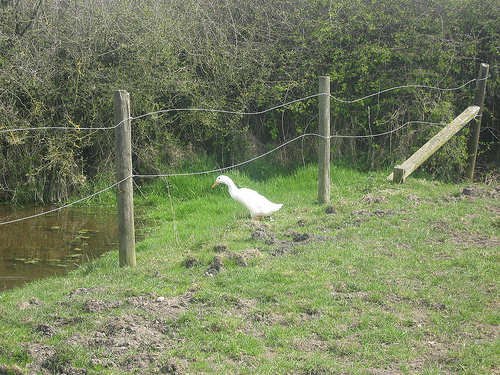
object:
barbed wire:
[0, 77, 491, 225]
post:
[465, 62, 490, 182]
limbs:
[73, 25, 151, 78]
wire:
[1, 124, 125, 133]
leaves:
[361, 32, 424, 59]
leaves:
[6, 224, 100, 268]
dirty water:
[0, 188, 134, 294]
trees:
[0, 0, 500, 207]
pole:
[318, 75, 331, 203]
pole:
[393, 166, 407, 185]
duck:
[210, 174, 283, 220]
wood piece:
[387, 105, 481, 182]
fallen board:
[385, 104, 481, 180]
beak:
[211, 181, 218, 188]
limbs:
[279, 0, 400, 168]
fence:
[0, 63, 490, 271]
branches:
[2, 0, 498, 165]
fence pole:
[112, 88, 138, 266]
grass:
[0, 157, 499, 375]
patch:
[70, 213, 500, 375]